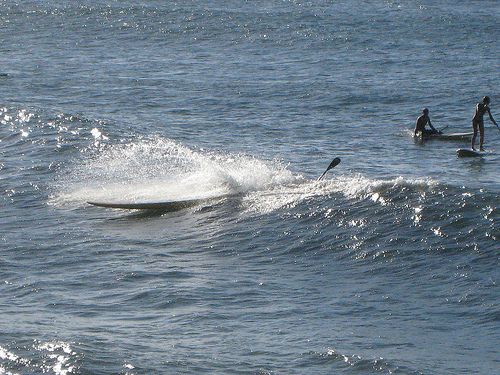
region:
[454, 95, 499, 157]
woman standing on a surfboard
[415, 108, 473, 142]
man holding onto surfboard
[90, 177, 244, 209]
surfboard on a wave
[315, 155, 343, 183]
paddle sticking out of ocean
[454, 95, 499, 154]
skinny woman standing on surfboard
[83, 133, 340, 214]
surfboard and paddle in a wave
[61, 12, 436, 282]
this is an ocean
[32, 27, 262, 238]
the water is blue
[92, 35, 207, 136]
the water is deep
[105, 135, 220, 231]
the waves are breaking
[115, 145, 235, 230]
the waves are white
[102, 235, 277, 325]
the waves are small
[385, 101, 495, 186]
there are two surfers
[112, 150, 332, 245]
this board is abandoned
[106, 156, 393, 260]
this board is long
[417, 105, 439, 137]
Person sitting on a surfboard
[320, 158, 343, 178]
Paddle sticking out of the water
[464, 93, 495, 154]
Person standing on a surfboard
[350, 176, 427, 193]
White foamy water on wave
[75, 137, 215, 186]
Water splash from wave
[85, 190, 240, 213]
Kayak in the water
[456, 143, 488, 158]
Surfboard under a person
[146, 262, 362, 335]
Water ripples in the ocean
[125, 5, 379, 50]
Sparkling water in the ocean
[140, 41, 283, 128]
Large body of blue water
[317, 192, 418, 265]
Ripples in the water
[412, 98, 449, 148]
A person sitting on a surfboard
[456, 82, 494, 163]
A person standing on a surfboard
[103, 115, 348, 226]
Crash in the water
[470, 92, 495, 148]
The person is wearing a bathing suit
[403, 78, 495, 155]
Two people in the water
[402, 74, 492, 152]
Two people in a body of water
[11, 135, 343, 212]
Kayak without rider hit by wave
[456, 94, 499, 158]
Person standing on board in the water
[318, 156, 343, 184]
Single paddle sticking out of the water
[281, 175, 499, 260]
Sun reflecting off of wave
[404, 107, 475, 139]
Man sitting in kayak in the water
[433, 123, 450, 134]
Paddle in man's hand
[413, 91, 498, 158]
Two people next to each other in the water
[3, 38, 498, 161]
Two people floating in calm water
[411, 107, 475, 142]
Person sitting and holding paddle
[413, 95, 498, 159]
Person standing next to person sitting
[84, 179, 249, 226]
white surf board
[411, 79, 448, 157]
surfer on board in ocean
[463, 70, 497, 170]
surfer on board in ocean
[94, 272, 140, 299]
white and blue ocean waves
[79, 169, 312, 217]
the surfboard is on the wave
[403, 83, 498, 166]
people is on the water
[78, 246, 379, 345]
ripples in the ocean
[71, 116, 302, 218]
a splash over a surfboard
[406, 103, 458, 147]
person is sit on a surfboard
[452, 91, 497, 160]
person stands on the water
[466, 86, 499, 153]
person is bend forward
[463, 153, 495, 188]
reflection on the water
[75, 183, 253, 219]
the surfboard is empty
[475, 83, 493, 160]
A person is playing.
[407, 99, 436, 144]
A person is playing.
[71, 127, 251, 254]
A wave in the water.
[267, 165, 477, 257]
A wave in the water.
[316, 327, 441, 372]
A wave in the water.